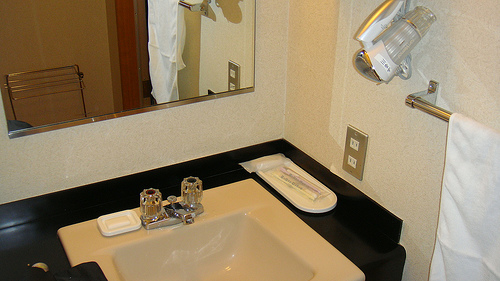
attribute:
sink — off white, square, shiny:
[57, 177, 366, 281]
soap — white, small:
[106, 217, 130, 228]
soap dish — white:
[97, 209, 142, 239]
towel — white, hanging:
[428, 111, 499, 280]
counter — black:
[0, 156, 406, 280]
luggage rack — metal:
[3, 64, 88, 120]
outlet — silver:
[341, 125, 368, 182]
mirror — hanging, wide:
[0, 1, 258, 139]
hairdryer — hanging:
[353, 0, 437, 87]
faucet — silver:
[165, 202, 196, 226]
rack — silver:
[406, 80, 452, 124]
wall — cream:
[284, 0, 499, 281]